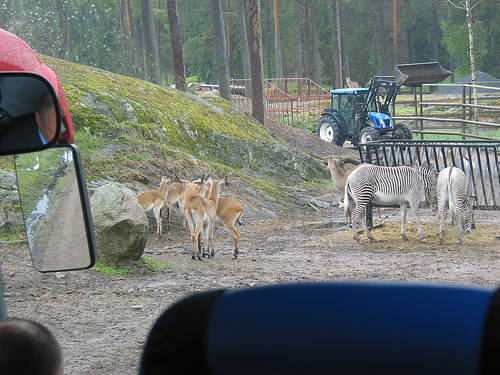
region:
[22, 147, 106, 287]
this is a mirror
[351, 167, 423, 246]
this is a zebra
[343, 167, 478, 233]
the zebras are two in number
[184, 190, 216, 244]
this is an antelope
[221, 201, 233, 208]
the antelope is brown in color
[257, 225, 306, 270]
this is the ground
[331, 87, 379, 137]
this is a tractor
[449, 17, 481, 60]
this is a tree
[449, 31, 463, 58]
the tree has green leaves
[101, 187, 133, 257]
this is a rock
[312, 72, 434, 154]
a bright blue vehicle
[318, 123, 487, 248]
a couple of zebras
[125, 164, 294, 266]
a group of antelope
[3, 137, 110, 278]
a side view mirror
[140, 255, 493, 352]
the back of a chair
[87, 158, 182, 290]
a large grey boulder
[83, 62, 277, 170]
some moss covered rock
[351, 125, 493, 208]
a black metal feeder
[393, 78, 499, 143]
a tall fence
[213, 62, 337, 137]
a red metal enclosure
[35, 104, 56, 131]
this is a man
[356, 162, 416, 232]
this is a zebra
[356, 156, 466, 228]
the zebra are two in number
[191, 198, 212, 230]
this is an antelope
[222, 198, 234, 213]
the antelope is brown in color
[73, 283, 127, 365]
this is the ground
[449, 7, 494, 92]
this is a tree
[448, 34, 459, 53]
the tree has green leaves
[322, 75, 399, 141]
this is a bulldozer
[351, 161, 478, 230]
these are two zebras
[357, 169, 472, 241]
the zebras are feeding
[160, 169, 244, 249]
these are antelopes in one place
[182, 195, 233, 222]
the antelopes are brown in color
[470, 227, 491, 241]
the grass are dry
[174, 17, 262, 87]
the trees are tall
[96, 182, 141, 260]
the rock is large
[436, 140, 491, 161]
this is a fence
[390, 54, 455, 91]
the crane is up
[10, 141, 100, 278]
Rearview mirror on vehicle.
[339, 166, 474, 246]
Zebra facing away from camera.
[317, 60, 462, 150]
Blue tractor in the background.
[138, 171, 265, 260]
Group of brown animals.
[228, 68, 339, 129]
Red fencing in the background.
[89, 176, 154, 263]
Large rock next to animals.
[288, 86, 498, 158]
Metal fencing by the animals.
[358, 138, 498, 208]
Metal feeding area for animals.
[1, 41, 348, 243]
Hill with green moss.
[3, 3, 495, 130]
Trees in the background.